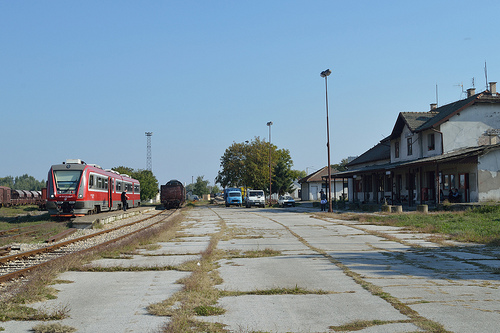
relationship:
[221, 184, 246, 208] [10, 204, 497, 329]
truck on road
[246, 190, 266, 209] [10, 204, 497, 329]
truck parked on the road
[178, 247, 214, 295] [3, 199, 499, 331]
patch of grass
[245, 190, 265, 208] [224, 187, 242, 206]
truck parked by truck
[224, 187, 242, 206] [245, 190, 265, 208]
truck parked by truck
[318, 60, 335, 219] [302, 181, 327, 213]
light pole next to man